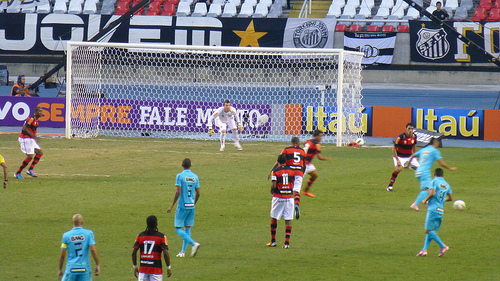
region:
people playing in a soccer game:
[3, 6, 498, 278]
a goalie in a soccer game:
[210, 97, 249, 155]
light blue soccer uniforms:
[415, 140, 452, 255]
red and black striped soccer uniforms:
[271, 142, 310, 212]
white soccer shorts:
[270, 192, 300, 222]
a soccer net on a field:
[57, 31, 369, 153]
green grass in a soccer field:
[33, 149, 260, 275]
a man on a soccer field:
[167, 152, 212, 261]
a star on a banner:
[230, 17, 270, 47]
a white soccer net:
[58, 36, 372, 148]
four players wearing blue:
[56, 137, 454, 279]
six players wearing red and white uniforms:
[14, 103, 421, 279]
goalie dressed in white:
[202, 98, 244, 153]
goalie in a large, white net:
[57, 36, 366, 147]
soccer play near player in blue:
[450, 195, 467, 211]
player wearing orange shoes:
[298, 188, 313, 200]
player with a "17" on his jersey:
[139, 238, 154, 257]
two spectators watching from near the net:
[9, 72, 30, 98]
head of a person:
[174, 154, 201, 171]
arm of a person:
[165, 186, 182, 216]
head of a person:
[49, 200, 106, 234]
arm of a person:
[50, 243, 71, 278]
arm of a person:
[87, 229, 113, 277]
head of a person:
[134, 198, 166, 235]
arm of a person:
[128, 238, 142, 268]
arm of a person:
[152, 230, 186, 274]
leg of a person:
[264, 208, 284, 248]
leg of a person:
[277, 204, 309, 266]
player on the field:
[265, 147, 304, 253]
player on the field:
[423, 169, 448, 261]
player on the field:
[155, 140, 207, 260]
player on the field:
[129, 220, 173, 279]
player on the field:
[57, 211, 97, 276]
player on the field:
[158, 138, 205, 245]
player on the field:
[206, 97, 241, 157]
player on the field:
[18, 110, 58, 175]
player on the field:
[385, 120, 414, 192]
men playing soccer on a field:
[1, 100, 452, 277]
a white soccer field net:
[68, 40, 365, 147]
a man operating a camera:
[12, 74, 32, 97]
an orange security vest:
[9, 84, 30, 96]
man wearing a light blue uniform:
[176, 170, 201, 249]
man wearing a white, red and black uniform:
[268, 163, 298, 243]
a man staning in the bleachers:
[429, 1, 448, 21]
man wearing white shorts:
[269, 194, 295, 220]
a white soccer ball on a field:
[453, 196, 466, 211]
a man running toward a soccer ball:
[303, 128, 327, 198]